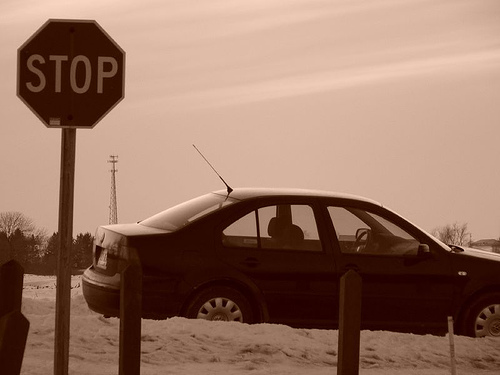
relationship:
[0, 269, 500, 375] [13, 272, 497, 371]
snow on ground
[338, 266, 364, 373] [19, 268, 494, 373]
pole in snow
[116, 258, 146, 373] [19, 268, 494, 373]
pole in snow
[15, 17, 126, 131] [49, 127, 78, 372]
stop sign with pole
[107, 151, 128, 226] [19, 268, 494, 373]
electric post in snow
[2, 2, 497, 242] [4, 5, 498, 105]
sky with clouds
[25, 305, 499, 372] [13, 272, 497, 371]
snow on ground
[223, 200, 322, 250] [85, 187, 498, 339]
window on car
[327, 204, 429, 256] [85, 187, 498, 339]
window on car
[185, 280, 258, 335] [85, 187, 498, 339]
wheel of car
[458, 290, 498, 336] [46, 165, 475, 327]
wheel of car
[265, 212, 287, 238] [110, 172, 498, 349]
headrest of car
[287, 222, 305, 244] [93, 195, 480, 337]
headrest of car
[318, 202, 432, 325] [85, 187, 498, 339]
passenger door of car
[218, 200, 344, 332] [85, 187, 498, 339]
door of car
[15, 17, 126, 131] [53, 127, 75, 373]
stop sign on pole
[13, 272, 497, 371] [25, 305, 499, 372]
ground covered with snow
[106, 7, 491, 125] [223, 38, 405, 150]
clouds in sky